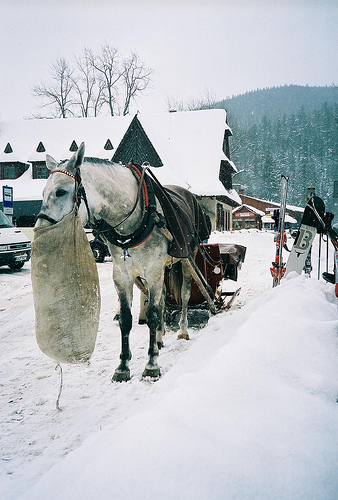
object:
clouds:
[0, 0, 337, 119]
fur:
[96, 174, 130, 201]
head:
[32, 141, 91, 232]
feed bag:
[29, 203, 100, 365]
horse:
[17, 106, 302, 361]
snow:
[0, 229, 338, 499]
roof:
[232, 203, 266, 217]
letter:
[294, 228, 313, 253]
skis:
[270, 174, 291, 288]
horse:
[30, 148, 211, 385]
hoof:
[142, 355, 161, 384]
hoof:
[112, 362, 131, 383]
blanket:
[154, 184, 212, 258]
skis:
[282, 195, 326, 278]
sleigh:
[163, 243, 247, 331]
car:
[0, 206, 32, 272]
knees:
[119, 305, 159, 331]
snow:
[0, 109, 243, 208]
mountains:
[187, 84, 338, 237]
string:
[52, 362, 65, 410]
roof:
[0, 110, 165, 203]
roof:
[137, 107, 242, 207]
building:
[232, 182, 305, 230]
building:
[133, 108, 243, 233]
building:
[0, 112, 166, 227]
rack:
[324, 211, 335, 286]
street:
[1, 218, 338, 500]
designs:
[125, 132, 147, 163]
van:
[0, 207, 33, 272]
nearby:
[0, 336, 35, 400]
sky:
[0, 0, 338, 144]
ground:
[0, 231, 338, 500]